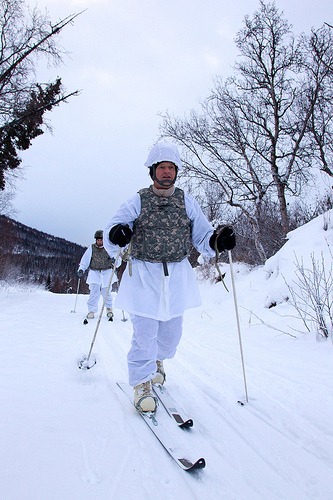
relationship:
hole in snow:
[267, 299, 277, 309] [1, 208, 331, 498]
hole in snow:
[268, 271, 273, 274] [1, 208, 331, 498]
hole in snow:
[283, 295, 289, 302] [1, 208, 331, 498]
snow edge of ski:
[0, 292, 332, 498] [116, 379, 205, 472]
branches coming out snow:
[290, 247, 326, 301] [223, 275, 325, 370]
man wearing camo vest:
[103, 135, 236, 418] [129, 187, 192, 264]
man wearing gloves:
[69, 94, 255, 393] [91, 199, 247, 263]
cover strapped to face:
[144, 141, 184, 170] [153, 161, 179, 185]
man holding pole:
[103, 135, 236, 418] [225, 245, 251, 403]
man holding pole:
[103, 135, 236, 418] [87, 251, 118, 368]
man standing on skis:
[103, 135, 236, 418] [115, 376, 205, 471]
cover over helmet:
[144, 141, 184, 170] [142, 137, 186, 169]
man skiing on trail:
[103, 135, 236, 418] [219, 421, 303, 499]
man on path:
[103, 135, 236, 418] [86, 335, 265, 475]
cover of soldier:
[144, 141, 184, 170] [109, 124, 232, 461]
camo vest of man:
[129, 187, 192, 264] [103, 135, 236, 418]